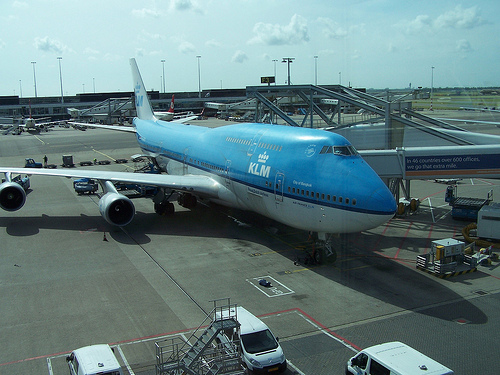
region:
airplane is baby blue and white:
[262, 148, 326, 225]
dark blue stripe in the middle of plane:
[253, 168, 291, 209]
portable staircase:
[178, 310, 278, 367]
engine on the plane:
[93, 191, 154, 233]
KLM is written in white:
[246, 156, 280, 183]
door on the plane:
[271, 164, 292, 204]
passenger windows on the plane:
[282, 183, 370, 208]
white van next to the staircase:
[227, 316, 293, 374]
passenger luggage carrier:
[53, 145, 84, 164]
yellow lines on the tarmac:
[253, 228, 326, 282]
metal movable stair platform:
[148, 290, 260, 371]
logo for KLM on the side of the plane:
[232, 142, 285, 191]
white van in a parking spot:
[203, 298, 301, 374]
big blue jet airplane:
[1, 74, 411, 276]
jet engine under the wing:
[81, 170, 145, 238]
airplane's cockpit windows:
[303, 126, 372, 172]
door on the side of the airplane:
[268, 170, 286, 207]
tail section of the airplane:
[58, 45, 200, 137]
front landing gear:
[291, 233, 341, 273]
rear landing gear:
[141, 182, 203, 227]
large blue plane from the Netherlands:
[2, 57, 499, 259]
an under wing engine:
[96, 184, 138, 237]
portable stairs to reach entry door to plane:
[163, 299, 243, 374]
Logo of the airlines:
[238, 134, 282, 192]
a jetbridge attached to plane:
[369, 132, 497, 202]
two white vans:
[213, 299, 468, 371]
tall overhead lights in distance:
[9, 47, 451, 95]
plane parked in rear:
[3, 112, 76, 144]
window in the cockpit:
[305, 139, 367, 171]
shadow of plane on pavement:
[0, 204, 490, 351]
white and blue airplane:
[19, 63, 411, 260]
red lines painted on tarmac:
[230, 217, 450, 367]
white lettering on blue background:
[231, 145, 279, 182]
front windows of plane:
[320, 143, 357, 163]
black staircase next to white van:
[152, 295, 237, 371]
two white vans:
[205, 293, 456, 374]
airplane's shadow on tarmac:
[8, 202, 484, 331]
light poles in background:
[18, 49, 451, 96]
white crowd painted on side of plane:
[252, 145, 276, 166]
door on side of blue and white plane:
[268, 169, 285, 205]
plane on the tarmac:
[0, 56, 415, 270]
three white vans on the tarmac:
[57, 296, 478, 373]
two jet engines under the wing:
[2, 169, 157, 246]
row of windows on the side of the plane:
[286, 185, 356, 212]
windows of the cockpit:
[314, 142, 364, 164]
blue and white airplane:
[0, 58, 403, 262]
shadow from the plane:
[0, 206, 485, 341]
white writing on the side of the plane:
[243, 161, 275, 181]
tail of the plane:
[60, 56, 202, 159]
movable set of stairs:
[159, 304, 244, 374]